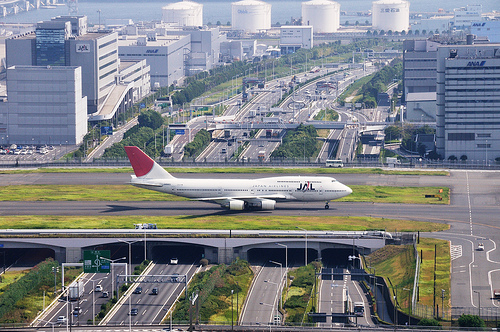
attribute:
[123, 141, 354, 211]
plane — white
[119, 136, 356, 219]
plane — white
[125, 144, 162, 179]
wing tip — red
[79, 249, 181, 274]
traffic — auto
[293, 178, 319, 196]
logo — Japan Airlines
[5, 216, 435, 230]
grass — green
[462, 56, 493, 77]
logo — gray, green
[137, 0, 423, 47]
structures — 4 round white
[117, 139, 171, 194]
tail — red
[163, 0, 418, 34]
tanks — white